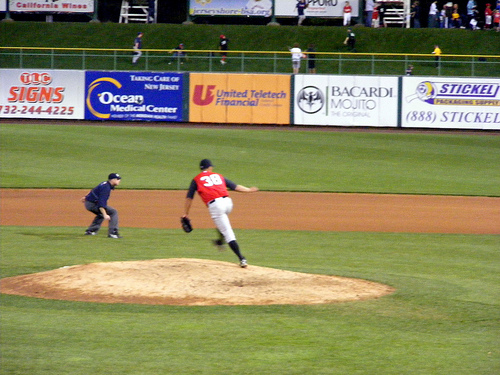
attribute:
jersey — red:
[184, 173, 236, 209]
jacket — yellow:
[431, 47, 438, 57]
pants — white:
[210, 197, 241, 251]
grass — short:
[372, 320, 472, 372]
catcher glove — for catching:
[177, 215, 195, 235]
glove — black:
[174, 214, 197, 236]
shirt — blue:
[84, 184, 113, 205]